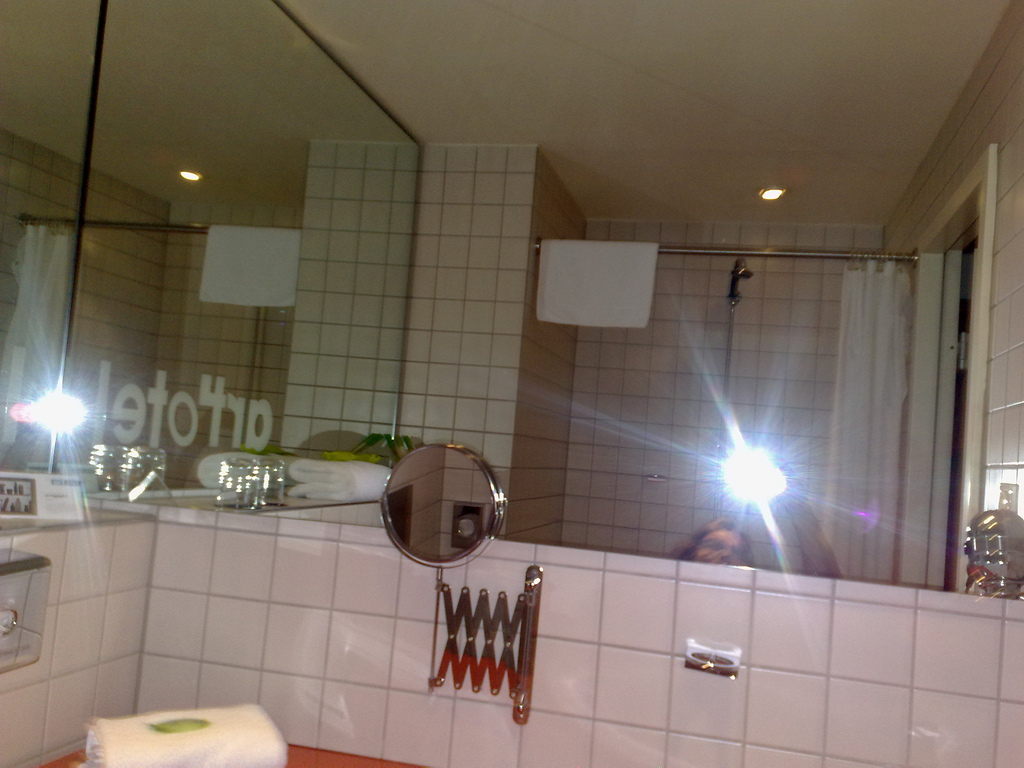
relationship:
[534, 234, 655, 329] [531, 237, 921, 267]
towel hanging on curtain rod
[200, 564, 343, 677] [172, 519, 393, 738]
tile on wall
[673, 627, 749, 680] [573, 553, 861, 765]
dish on wall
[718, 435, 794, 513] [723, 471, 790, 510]
flash from camera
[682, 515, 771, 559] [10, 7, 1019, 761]
person taking picture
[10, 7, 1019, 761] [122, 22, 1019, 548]
picture in mirror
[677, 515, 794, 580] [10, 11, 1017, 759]
person taking photo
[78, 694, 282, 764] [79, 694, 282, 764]
towels on towels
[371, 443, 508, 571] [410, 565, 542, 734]
mirror on holder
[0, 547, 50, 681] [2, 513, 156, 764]
tissue box on wall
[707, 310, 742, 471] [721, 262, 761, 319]
waterline leading up to shower head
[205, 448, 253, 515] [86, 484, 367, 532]
glass on shelf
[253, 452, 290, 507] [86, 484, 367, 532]
glass on shelf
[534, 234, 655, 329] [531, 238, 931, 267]
towel on curtain rod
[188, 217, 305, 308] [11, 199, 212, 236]
towel on curtain rod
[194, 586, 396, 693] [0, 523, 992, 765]
tiles on wall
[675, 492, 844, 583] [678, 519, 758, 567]
person has a head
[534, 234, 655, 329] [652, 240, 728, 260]
towel hanging on curtain rod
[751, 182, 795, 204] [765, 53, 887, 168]
circle on ceiling